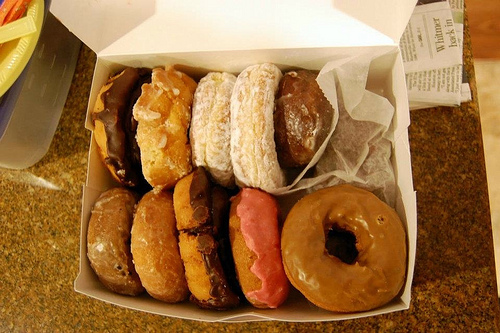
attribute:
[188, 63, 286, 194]
doughnuts — sugar-coated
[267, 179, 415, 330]
doughnut — maple, frosted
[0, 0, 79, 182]
bucket — plastic, food bucket, transparent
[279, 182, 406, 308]
doughnut — brown, frosted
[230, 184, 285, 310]
doughnut — frosted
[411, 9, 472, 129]
newspaper — beside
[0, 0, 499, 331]
counter-top — granite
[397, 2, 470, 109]
newspaper — folded in half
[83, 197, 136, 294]
doughnut — glazed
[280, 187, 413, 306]
frosting — brown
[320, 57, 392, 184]
tissue — crumbled up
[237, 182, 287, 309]
pink frosting — strawberryesque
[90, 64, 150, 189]
frosting — chocolate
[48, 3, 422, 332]
box — cardboard, white